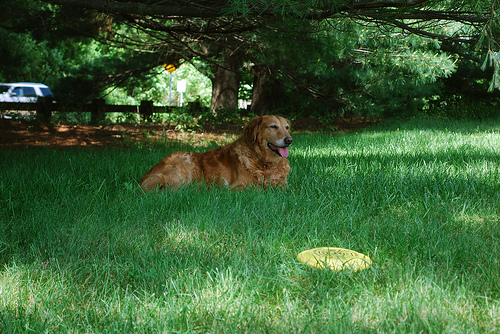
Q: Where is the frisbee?
A: In the grass.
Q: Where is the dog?
A: In the grass.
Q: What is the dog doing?
A: Laying.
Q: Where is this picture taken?
A: In a park.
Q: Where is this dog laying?
A: In the grass.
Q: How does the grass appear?
A: Long.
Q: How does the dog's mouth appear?
A: Open.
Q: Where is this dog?
A: Under trees.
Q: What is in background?
A: Wooden post fence.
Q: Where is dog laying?
A: Grass area.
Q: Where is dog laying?
A: Grassy area.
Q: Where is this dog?
A: Under a tree.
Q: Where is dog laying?
A: In the shade.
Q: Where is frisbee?
A: On the ground.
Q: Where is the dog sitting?
A: In the grass.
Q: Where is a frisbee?
A: On grass.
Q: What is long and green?
A: Grass.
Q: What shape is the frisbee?
A: Round.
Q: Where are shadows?
A: On the grass.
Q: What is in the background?
A: Trees.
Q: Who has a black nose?
A: Dog.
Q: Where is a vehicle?
A: On the road.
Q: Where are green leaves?
A: On trees.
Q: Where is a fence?
A: In the distance.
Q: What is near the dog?
A: A frisbee.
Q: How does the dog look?
A: Content.